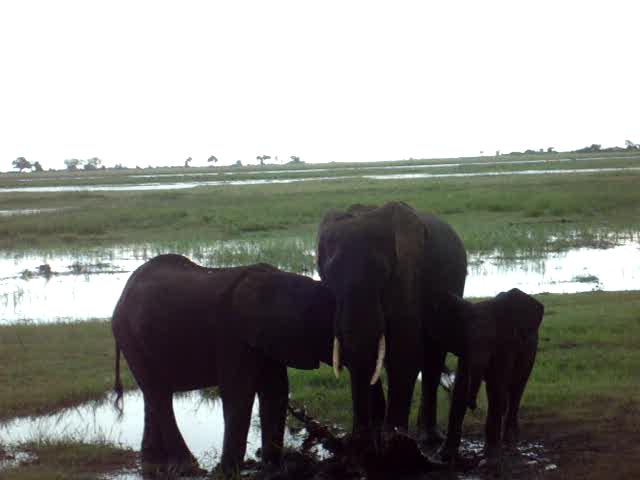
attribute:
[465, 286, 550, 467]
elephant — gray , large 